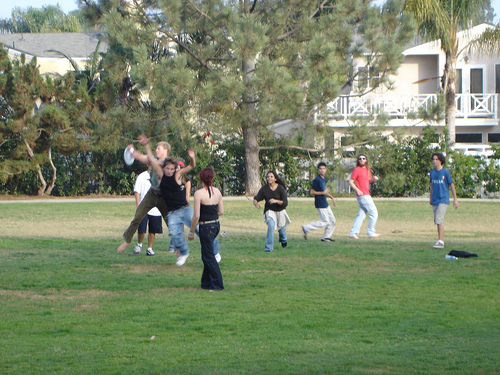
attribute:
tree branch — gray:
[233, 0, 266, 197]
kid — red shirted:
[301, 164, 338, 239]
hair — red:
[198, 164, 216, 194]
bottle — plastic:
[438, 252, 461, 263]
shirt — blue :
[431, 165, 456, 202]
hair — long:
[356, 152, 367, 170]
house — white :
[276, 21, 495, 156]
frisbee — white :
[109, 137, 141, 167]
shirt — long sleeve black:
[253, 182, 292, 210]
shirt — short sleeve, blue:
[425, 164, 455, 204]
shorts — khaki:
[427, 200, 449, 225]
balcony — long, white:
[310, 89, 498, 129]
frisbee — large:
[122, 143, 138, 167]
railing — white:
[310, 92, 498, 121]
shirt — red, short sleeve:
[350, 161, 390, 203]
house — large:
[295, 22, 496, 188]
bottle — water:
[441, 253, 463, 264]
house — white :
[325, 13, 500, 180]